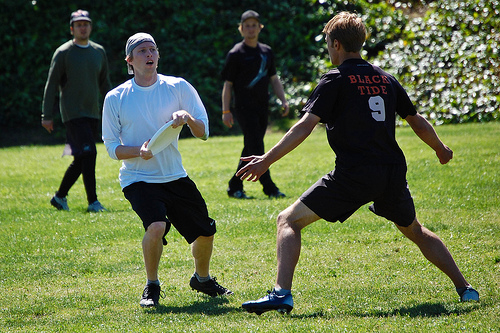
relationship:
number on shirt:
[369, 91, 388, 125] [302, 54, 418, 174]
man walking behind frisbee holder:
[44, 7, 111, 212] [97, 29, 229, 308]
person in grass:
[221, 8, 291, 199] [1, 132, 484, 329]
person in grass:
[237, 11, 482, 311] [213, 192, 496, 313]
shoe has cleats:
[241, 295, 293, 317] [256, 304, 294, 318]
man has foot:
[220, 7, 481, 312] [241, 288, 293, 312]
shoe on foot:
[241, 295, 293, 317] [241, 288, 293, 312]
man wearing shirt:
[220, 7, 481, 312] [298, 61, 420, 181]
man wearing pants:
[220, 7, 481, 312] [299, 150, 418, 230]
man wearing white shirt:
[101, 32, 234, 308] [102, 73, 209, 190]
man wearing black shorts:
[101, 32, 234, 308] [123, 175, 217, 245]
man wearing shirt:
[220, 7, 481, 312] [304, 50, 418, 158]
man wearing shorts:
[220, 7, 481, 312] [291, 153, 427, 223]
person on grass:
[37, 4, 122, 207] [1, 132, 484, 329]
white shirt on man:
[102, 73, 209, 190] [101, 33, 223, 298]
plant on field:
[0, 2, 497, 117] [4, 137, 496, 329]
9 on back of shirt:
[366, 95, 386, 122] [299, 56, 428, 178]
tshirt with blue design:
[227, 49, 277, 107] [253, 55, 270, 83]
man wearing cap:
[44, 7, 111, 212] [65, 5, 97, 27]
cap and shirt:
[65, 5, 97, 27] [46, 39, 110, 141]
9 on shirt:
[366, 95, 386, 122] [304, 59, 416, 169]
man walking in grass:
[44, 7, 111, 212] [1, 132, 484, 329]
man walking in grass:
[218, 8, 290, 202] [1, 132, 484, 329]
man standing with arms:
[220, 7, 481, 312] [226, 81, 454, 189]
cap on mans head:
[65, 5, 97, 27] [62, 5, 94, 21]